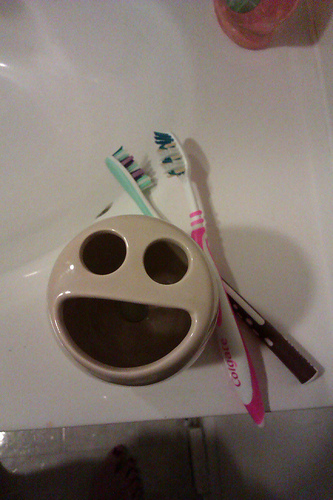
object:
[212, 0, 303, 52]
bottle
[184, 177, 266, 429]
handle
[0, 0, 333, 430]
toothbrush holder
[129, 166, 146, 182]
purple bristle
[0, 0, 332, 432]
counter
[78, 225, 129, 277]
holes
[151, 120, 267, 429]
toothbrush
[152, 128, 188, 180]
bristles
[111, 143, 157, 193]
bristles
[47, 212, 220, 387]
holder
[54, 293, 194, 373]
semi-circle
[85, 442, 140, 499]
foot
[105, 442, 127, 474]
toes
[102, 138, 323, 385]
brush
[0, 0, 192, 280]
sink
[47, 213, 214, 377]
face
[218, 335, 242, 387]
colgate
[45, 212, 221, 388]
cup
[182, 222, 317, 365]
shadow